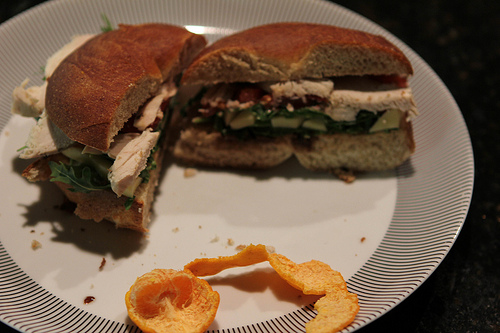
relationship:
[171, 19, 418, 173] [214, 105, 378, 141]
burger has veggies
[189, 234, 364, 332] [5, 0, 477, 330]
peel on plate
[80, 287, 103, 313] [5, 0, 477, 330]
sauce on plate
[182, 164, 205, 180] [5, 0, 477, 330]
crumb on plate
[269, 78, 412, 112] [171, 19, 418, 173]
chicken on burger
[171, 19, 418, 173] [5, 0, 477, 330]
burger on plate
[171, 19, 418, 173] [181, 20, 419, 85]
burger has bread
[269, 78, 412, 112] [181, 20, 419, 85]
chicken on bread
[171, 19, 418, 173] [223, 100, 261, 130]
burger has cucumber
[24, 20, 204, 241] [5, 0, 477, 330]
burger on plate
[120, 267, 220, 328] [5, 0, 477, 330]
clementine on plate